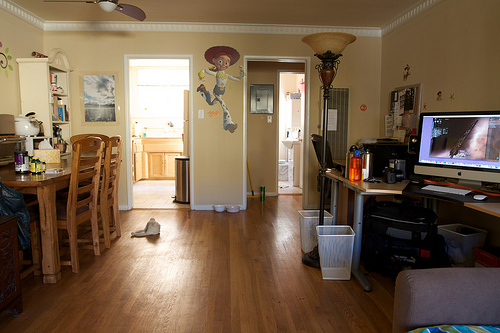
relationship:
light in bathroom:
[278, 76, 302, 167] [278, 72, 303, 194]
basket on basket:
[293, 193, 340, 269] [309, 219, 371, 287]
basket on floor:
[309, 219, 371, 287] [243, 195, 380, 331]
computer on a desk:
[415, 90, 498, 179] [325, 160, 499, 293]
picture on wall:
[195, 42, 245, 132] [43, 29, 378, 209]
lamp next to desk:
[297, 27, 362, 272] [319, 150, 499, 276]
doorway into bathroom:
[237, 52, 309, 213] [275, 66, 306, 197]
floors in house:
[183, 208, 283, 328] [0, 3, 484, 318]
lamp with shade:
[297, 27, 362, 272] [301, 29, 357, 56]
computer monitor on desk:
[414, 108, 484, 174] [5, 126, 137, 251]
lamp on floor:
[297, 27, 362, 272] [186, 215, 276, 329]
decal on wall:
[195, 41, 245, 136] [378, 33, 477, 103]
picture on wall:
[82, 72, 117, 122] [1, 3, 498, 210]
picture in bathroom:
[82, 72, 117, 122] [278, 72, 303, 194]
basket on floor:
[315, 225, 355, 280] [2, 179, 493, 328]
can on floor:
[171, 151, 191, 211] [206, 232, 325, 310]